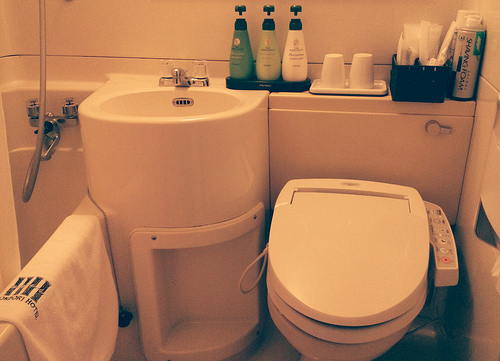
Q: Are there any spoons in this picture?
A: No, there are no spoons.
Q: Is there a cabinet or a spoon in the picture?
A: No, there are no spoons or cabinets.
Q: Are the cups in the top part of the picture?
A: Yes, the cups are in the top of the image.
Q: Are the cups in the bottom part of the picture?
A: No, the cups are in the top of the image.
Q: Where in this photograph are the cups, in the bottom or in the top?
A: The cups are in the top of the image.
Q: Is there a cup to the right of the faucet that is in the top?
A: Yes, there are cups to the right of the tap.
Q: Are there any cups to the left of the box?
A: Yes, there are cups to the left of the box.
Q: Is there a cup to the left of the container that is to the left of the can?
A: Yes, there are cups to the left of the box.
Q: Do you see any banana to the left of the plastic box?
A: No, there are cups to the left of the box.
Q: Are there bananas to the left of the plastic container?
A: No, there are cups to the left of the box.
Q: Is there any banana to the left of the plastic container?
A: No, there are cups to the left of the box.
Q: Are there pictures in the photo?
A: No, there are no pictures.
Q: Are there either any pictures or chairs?
A: No, there are no pictures or chairs.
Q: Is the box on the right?
A: Yes, the box is on the right of the image.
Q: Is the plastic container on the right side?
A: Yes, the box is on the right of the image.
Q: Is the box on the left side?
A: No, the box is on the right of the image.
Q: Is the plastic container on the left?
A: No, the box is on the right of the image.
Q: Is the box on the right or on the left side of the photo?
A: The box is on the right of the image.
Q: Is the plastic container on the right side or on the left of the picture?
A: The box is on the right of the image.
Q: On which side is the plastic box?
A: The box is on the right of the image.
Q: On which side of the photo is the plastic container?
A: The box is on the right of the image.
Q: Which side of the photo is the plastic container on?
A: The box is on the right of the image.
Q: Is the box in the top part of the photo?
A: Yes, the box is in the top of the image.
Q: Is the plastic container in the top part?
A: Yes, the box is in the top of the image.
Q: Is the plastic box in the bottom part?
A: No, the box is in the top of the image.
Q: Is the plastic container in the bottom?
A: No, the box is in the top of the image.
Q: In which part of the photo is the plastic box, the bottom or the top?
A: The box is in the top of the image.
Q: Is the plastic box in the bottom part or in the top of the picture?
A: The box is in the top of the image.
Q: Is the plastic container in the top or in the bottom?
A: The box is in the top of the image.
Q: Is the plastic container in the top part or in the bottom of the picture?
A: The box is in the top of the image.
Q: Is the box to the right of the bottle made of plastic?
A: Yes, the box is made of plastic.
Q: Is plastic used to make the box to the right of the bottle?
A: Yes, the box is made of plastic.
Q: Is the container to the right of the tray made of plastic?
A: Yes, the box is made of plastic.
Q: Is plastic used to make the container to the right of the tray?
A: Yes, the box is made of plastic.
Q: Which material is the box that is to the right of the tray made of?
A: The box is made of plastic.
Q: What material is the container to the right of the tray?
A: The box is made of plastic.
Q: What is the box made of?
A: The box is made of plastic.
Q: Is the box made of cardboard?
A: No, the box is made of plastic.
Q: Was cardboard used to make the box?
A: No, the box is made of plastic.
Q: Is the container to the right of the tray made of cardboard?
A: No, the box is made of plastic.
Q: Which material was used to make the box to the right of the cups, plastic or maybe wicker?
A: The box is made of plastic.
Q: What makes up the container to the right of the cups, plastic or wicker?
A: The box is made of plastic.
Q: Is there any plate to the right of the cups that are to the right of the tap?
A: No, there is a box to the right of the cups.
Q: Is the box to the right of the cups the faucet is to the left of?
A: Yes, the box is to the right of the cups.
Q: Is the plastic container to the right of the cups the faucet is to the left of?
A: Yes, the box is to the right of the cups.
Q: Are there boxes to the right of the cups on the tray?
A: Yes, there is a box to the right of the cups.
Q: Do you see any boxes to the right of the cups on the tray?
A: Yes, there is a box to the right of the cups.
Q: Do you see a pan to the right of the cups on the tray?
A: No, there is a box to the right of the cups.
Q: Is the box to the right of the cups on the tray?
A: Yes, the box is to the right of the cups.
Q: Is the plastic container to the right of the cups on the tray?
A: Yes, the box is to the right of the cups.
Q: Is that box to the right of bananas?
A: No, the box is to the right of the cups.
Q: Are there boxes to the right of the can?
A: No, the box is to the left of the can.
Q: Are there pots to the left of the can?
A: No, there is a box to the left of the can.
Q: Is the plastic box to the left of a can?
A: Yes, the box is to the left of a can.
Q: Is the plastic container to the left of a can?
A: Yes, the box is to the left of a can.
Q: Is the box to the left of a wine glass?
A: No, the box is to the left of a can.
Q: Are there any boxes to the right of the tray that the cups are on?
A: Yes, there is a box to the right of the tray.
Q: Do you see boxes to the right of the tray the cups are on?
A: Yes, there is a box to the right of the tray.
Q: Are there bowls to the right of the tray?
A: No, there is a box to the right of the tray.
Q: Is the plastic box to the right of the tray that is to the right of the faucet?
A: Yes, the box is to the right of the tray.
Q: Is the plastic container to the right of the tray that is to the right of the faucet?
A: Yes, the box is to the right of the tray.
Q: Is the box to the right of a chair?
A: No, the box is to the right of the tray.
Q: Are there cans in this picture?
A: Yes, there is a can.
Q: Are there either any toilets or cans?
A: Yes, there is a can.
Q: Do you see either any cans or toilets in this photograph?
A: Yes, there is a can.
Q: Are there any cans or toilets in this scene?
A: Yes, there is a can.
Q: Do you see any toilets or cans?
A: Yes, there is a can.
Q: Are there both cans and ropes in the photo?
A: No, there is a can but no ropes.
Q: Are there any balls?
A: No, there are no balls.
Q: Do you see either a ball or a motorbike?
A: No, there are no balls or motorcycles.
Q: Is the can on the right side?
A: Yes, the can is on the right of the image.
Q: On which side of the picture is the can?
A: The can is on the right of the image.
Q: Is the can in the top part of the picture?
A: Yes, the can is in the top of the image.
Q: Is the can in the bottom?
A: No, the can is in the top of the image.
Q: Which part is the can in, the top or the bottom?
A: The can is in the top of the image.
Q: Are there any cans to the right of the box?
A: Yes, there is a can to the right of the box.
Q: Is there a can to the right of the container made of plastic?
A: Yes, there is a can to the right of the box.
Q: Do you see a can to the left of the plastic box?
A: No, the can is to the right of the box.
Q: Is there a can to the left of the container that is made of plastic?
A: No, the can is to the right of the box.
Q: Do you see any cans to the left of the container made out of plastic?
A: No, the can is to the right of the box.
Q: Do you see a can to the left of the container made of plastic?
A: No, the can is to the right of the box.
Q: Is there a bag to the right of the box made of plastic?
A: No, there is a can to the right of the box.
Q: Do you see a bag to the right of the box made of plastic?
A: No, there is a can to the right of the box.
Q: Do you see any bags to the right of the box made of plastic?
A: No, there is a can to the right of the box.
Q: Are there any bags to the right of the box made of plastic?
A: No, there is a can to the right of the box.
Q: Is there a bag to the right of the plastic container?
A: No, there is a can to the right of the box.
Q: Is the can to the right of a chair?
A: No, the can is to the right of the box.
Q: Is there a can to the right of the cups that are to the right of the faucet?
A: Yes, there is a can to the right of the cups.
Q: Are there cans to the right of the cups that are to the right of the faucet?
A: Yes, there is a can to the right of the cups.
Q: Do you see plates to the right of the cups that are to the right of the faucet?
A: No, there is a can to the right of the cups.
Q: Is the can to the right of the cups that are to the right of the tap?
A: Yes, the can is to the right of the cups.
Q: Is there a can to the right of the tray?
A: Yes, there is a can to the right of the tray.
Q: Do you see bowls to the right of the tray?
A: No, there is a can to the right of the tray.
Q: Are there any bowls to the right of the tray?
A: No, there is a can to the right of the tray.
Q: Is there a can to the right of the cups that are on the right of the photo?
A: Yes, there is a can to the right of the cups.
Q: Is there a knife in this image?
A: No, there are no knives.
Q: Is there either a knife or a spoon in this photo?
A: No, there are no knives or spoons.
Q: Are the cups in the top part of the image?
A: Yes, the cups are in the top of the image.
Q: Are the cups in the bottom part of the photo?
A: No, the cups are in the top of the image.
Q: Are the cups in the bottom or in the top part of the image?
A: The cups are in the top of the image.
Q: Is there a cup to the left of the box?
A: Yes, there are cups to the left of the box.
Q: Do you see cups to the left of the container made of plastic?
A: Yes, there are cups to the left of the box.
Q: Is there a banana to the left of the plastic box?
A: No, there are cups to the left of the box.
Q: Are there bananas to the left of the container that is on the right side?
A: No, there are cups to the left of the box.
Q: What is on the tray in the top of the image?
A: The cups are on the tray.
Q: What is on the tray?
A: The cups are on the tray.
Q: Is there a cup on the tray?
A: Yes, there are cups on the tray.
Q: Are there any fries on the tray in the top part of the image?
A: No, there are cups on the tray.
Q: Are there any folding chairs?
A: No, there are no folding chairs.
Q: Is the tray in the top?
A: Yes, the tray is in the top of the image.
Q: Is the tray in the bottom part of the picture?
A: No, the tray is in the top of the image.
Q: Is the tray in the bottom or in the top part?
A: The tray is in the top of the image.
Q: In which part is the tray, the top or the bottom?
A: The tray is in the top of the image.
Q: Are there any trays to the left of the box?
A: Yes, there is a tray to the left of the box.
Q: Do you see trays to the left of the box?
A: Yes, there is a tray to the left of the box.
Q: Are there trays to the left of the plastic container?
A: Yes, there is a tray to the left of the box.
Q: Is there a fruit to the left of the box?
A: No, there is a tray to the left of the box.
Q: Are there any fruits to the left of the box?
A: No, there is a tray to the left of the box.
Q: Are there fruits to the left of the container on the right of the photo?
A: No, there is a tray to the left of the box.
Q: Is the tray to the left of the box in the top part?
A: Yes, the tray is to the left of the box.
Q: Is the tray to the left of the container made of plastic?
A: Yes, the tray is to the left of the box.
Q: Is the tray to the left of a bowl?
A: No, the tray is to the left of the box.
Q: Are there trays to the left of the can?
A: Yes, there is a tray to the left of the can.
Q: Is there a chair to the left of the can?
A: No, there is a tray to the left of the can.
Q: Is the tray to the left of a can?
A: Yes, the tray is to the left of a can.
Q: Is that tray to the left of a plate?
A: No, the tray is to the left of a can.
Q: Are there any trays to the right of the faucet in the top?
A: Yes, there is a tray to the right of the faucet.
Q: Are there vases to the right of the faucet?
A: No, there is a tray to the right of the faucet.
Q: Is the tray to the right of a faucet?
A: Yes, the tray is to the right of a faucet.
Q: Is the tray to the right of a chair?
A: No, the tray is to the right of a faucet.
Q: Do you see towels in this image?
A: Yes, there is a towel.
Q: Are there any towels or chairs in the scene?
A: Yes, there is a towel.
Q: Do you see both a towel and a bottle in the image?
A: Yes, there are both a towel and a bottle.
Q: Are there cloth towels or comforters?
A: Yes, there is a cloth towel.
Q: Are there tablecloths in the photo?
A: No, there are no tablecloths.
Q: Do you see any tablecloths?
A: No, there are no tablecloths.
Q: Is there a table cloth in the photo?
A: No, there are no tablecloths.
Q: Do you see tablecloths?
A: No, there are no tablecloths.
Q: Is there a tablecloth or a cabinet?
A: No, there are no tablecloths or cabinets.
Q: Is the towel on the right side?
A: No, the towel is on the left of the image.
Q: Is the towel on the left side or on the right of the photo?
A: The towel is on the left of the image.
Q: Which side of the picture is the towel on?
A: The towel is on the left of the image.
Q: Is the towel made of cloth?
A: Yes, the towel is made of cloth.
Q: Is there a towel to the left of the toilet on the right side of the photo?
A: Yes, there is a towel to the left of the toilet.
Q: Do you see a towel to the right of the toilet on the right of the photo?
A: No, the towel is to the left of the toilet.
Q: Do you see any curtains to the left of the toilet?
A: No, there is a towel to the left of the toilet.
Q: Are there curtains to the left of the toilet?
A: No, there is a towel to the left of the toilet.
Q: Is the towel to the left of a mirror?
A: No, the towel is to the left of the toilet.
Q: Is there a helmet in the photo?
A: No, there are no helmets.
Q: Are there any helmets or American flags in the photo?
A: No, there are no helmets or American flags.